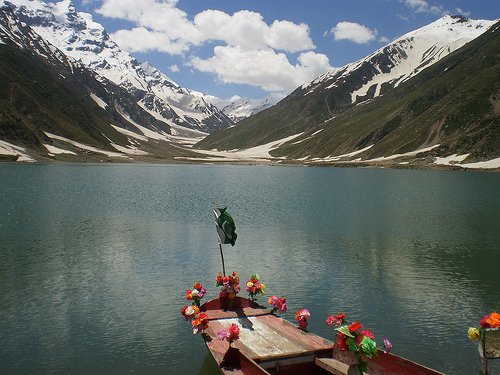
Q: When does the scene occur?
A: Daytime.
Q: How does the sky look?
A: Blue with a few clouds.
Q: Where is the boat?
A: In the water.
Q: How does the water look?
A: Very calm.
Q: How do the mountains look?
A: Covered with snow.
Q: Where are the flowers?
A: On the boat.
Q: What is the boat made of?
A: Wood.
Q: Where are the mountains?
A: In front of the boat.